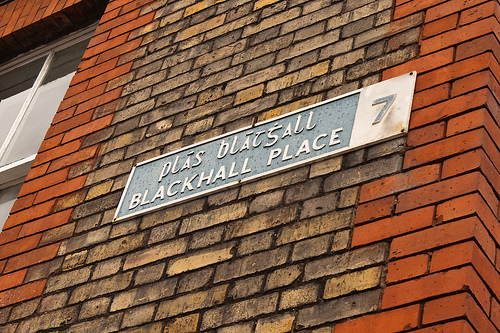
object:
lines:
[0, 50, 55, 155]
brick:
[123, 236, 189, 270]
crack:
[288, 272, 305, 285]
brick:
[263, 262, 304, 294]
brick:
[388, 216, 474, 260]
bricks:
[173, 296, 255, 332]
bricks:
[349, 176, 476, 281]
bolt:
[410, 72, 413, 75]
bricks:
[273, 262, 425, 333]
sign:
[111, 69, 415, 223]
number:
[371, 93, 397, 124]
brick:
[275, 205, 355, 248]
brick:
[82, 227, 151, 267]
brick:
[351, 205, 435, 249]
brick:
[110, 97, 156, 126]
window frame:
[7, 34, 67, 141]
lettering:
[117, 91, 359, 219]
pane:
[0, 34, 94, 168]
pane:
[0, 52, 51, 145]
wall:
[0, 0, 498, 333]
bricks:
[11, 226, 274, 333]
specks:
[332, 104, 351, 122]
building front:
[0, 0, 498, 333]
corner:
[459, 0, 498, 333]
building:
[0, 0, 500, 333]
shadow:
[0, 36, 100, 99]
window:
[0, 0, 109, 226]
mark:
[385, 111, 408, 134]